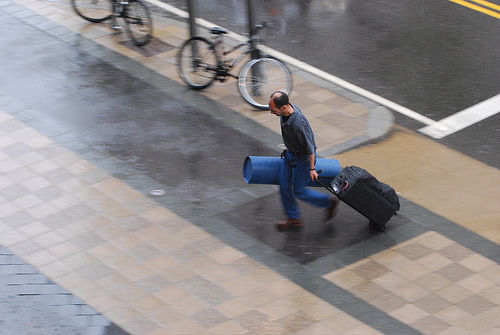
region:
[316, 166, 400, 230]
big black suitcase with handle and wheeks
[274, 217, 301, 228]
man's right brown leather shoe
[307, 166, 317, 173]
black banded watch on the man's left wrist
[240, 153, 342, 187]
blue case for some kind of project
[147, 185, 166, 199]
sewer cap on the brick walkway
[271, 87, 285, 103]
bald spot on the man's head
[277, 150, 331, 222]
semi baggy pair of blue jeans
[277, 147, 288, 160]
black cell phone clipped to the guys pants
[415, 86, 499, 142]
thick white crosswalk line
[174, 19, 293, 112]
women's mountain bike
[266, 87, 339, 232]
man seen from above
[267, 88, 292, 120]
man's dark hair is balding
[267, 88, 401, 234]
man pulling a large black rolling suitcase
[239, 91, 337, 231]
man carrying a large blue tube-like container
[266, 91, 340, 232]
man is in the act of walking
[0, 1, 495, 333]
brown and black tiled area beside street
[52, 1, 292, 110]
two bicycles leaning against poles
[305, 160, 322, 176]
man is wearing a watch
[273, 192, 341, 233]
man's brown shoes appear blurry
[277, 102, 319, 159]
man wearing a blue short-sleeved polo shirt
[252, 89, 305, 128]
a man with balding hair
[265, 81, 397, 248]
a man pulling a black suitcase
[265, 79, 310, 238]
a man wearing blue jeans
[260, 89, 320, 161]
a man wearing a grey shirt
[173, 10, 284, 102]
a bike leaned on pole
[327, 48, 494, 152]
white lines painted on a road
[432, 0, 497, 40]
yellow lines painted on a road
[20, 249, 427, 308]
a wet side walk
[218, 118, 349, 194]
a man carrying a blue container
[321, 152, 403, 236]
a black suitcase with wheels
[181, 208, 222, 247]
edge of a line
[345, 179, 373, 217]
part of a suiitcase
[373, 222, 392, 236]
part of a wheel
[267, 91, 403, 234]
man rolling suitcase with left hand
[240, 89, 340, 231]
man carrying large blue tube in right hand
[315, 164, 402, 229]
black rolling luggage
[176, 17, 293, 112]
bicycle parked on sidewalk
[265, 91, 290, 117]
man's partially-bald head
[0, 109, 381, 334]
walkway made of polished brown pavers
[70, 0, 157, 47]
bicycle parked on sidewalk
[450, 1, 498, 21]
double yellow line on asphalt street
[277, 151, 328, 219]
man is wearing blue jeans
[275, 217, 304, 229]
brown shoe on man's right foot